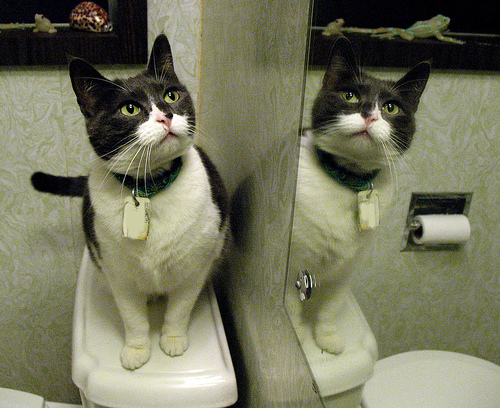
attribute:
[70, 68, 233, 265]
cat — looking, white, black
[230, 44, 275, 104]
wall — gold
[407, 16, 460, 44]
frog — green